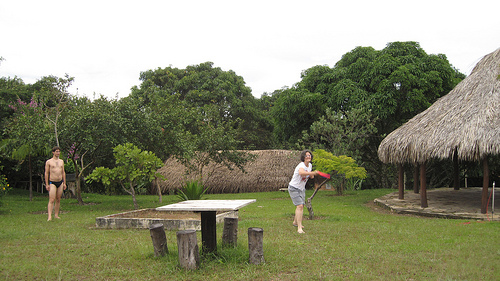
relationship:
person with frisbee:
[287, 150, 331, 234] [313, 161, 338, 177]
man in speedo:
[14, 138, 78, 250] [38, 175, 70, 195]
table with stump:
[164, 186, 260, 223] [236, 217, 270, 260]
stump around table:
[236, 217, 270, 260] [164, 186, 260, 223]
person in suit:
[287, 150, 331, 234] [288, 165, 330, 204]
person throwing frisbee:
[262, 147, 333, 238] [313, 161, 338, 177]